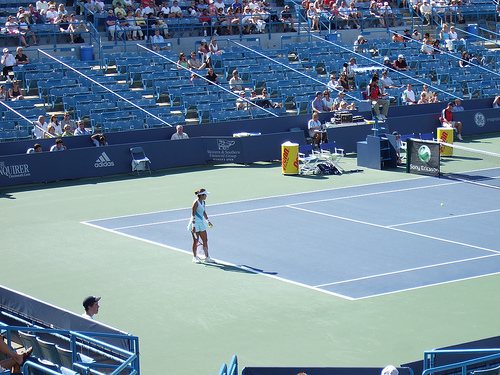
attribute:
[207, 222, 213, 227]
tennis ball — yellow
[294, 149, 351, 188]
chairs — white, stacked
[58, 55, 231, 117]
seats — blue, empty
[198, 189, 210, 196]
sun visor — white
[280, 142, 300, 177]
can — large, yellow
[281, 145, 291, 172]
letters — red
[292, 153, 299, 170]
letters — red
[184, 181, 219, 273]
player — female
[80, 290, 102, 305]
cap — black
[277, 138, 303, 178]
cooler — yellow